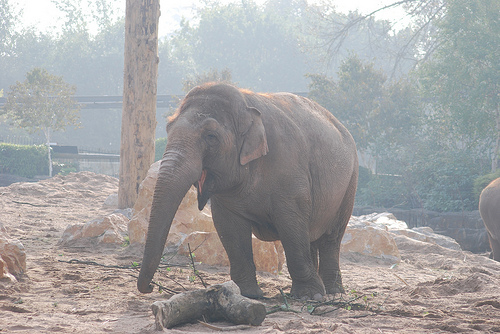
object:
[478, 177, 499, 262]
elephant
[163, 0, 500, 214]
trees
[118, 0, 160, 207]
pole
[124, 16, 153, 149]
tree bark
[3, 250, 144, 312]
dirt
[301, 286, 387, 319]
twigs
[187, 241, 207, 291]
twigs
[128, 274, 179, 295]
twigs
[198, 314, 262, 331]
twigs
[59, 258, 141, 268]
twigs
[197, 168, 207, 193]
tongue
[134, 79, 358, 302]
animal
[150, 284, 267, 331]
log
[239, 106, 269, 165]
ear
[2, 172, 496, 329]
ground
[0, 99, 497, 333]
enclosure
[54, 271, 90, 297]
foot prints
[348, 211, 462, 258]
rocks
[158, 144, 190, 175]
wrinkles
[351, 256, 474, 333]
sand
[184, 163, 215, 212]
mouth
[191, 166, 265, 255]
whimsical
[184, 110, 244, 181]
face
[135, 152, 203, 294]
trunk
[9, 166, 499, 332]
area